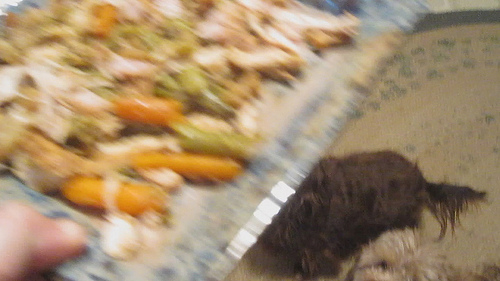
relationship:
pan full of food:
[0, 3, 427, 277] [2, 2, 345, 214]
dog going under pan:
[264, 149, 484, 281] [0, 0, 427, 281]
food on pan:
[0, 0, 271, 256] [0, 0, 427, 281]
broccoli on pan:
[152, 56, 235, 115] [0, 0, 427, 281]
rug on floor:
[327, 5, 499, 279] [287, 22, 484, 279]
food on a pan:
[0, 0, 271, 256] [0, 0, 427, 281]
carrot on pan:
[88, 2, 118, 38] [0, 0, 427, 281]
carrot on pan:
[111, 90, 191, 123] [0, 0, 427, 281]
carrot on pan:
[130, 149, 240, 179] [0, 0, 427, 281]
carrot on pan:
[68, 175, 158, 211] [0, 0, 427, 281]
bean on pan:
[174, 125, 254, 163] [0, 0, 427, 281]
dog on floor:
[259, 149, 488, 278] [276, 15, 493, 279]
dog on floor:
[259, 149, 488, 278] [226, 3, 498, 279]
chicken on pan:
[0, 0, 352, 214] [0, 0, 427, 281]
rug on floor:
[230, 0, 498, 281] [226, 3, 498, 279]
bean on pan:
[174, 125, 253, 153] [0, 0, 427, 281]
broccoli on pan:
[112, 19, 172, 53] [0, 0, 427, 281]